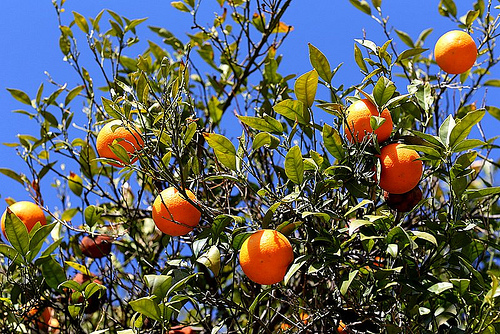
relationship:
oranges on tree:
[1, 28, 476, 291] [1, 2, 499, 326]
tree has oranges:
[1, 2, 499, 326] [1, 28, 476, 291]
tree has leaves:
[1, 2, 499, 326] [1, 1, 499, 321]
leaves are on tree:
[1, 1, 499, 321] [1, 2, 499, 326]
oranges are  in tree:
[1, 28, 476, 291] [1, 2, 499, 326]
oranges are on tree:
[1, 28, 476, 291] [1, 2, 499, 326]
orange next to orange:
[377, 138, 422, 192] [346, 98, 395, 143]